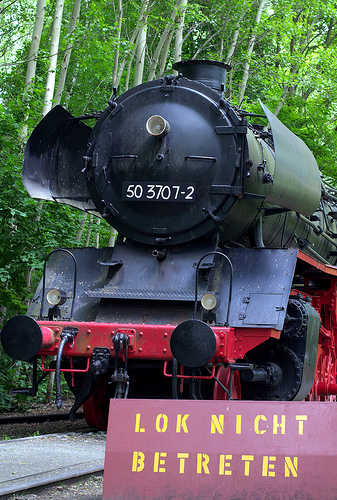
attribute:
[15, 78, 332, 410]
train — steam, green, red, old, black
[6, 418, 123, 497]
tracks — train, set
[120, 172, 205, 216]
number — white, handwritten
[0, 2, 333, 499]
photo — taken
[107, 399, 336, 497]
sign — german, rectangular, purple, red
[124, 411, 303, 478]
lettering — yellow, foreign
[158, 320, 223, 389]
object — black, round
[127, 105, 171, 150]
headlight — small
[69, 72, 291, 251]
tube — black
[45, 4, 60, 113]
trunk — white